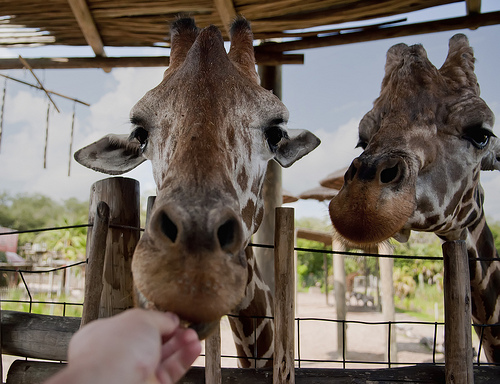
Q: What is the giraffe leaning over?
A: Fence.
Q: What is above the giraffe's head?
A: Roof.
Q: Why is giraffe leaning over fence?
A: Food.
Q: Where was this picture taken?
A: Zoo.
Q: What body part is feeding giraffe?
A: Hand.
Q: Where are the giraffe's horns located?
A: Head.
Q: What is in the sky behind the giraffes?
A: Clouds.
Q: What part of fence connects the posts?
A: Wire.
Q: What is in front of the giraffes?
A: A fence.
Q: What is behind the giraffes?
A: Wooden posts.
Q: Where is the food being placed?
A: In the giraffe's mouth.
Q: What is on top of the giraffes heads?
A: Horns.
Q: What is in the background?
A: Green trees.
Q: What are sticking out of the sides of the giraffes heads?
A: Ears.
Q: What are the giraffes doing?
A: Feeding.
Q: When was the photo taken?
A: Daytime.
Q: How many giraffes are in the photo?
A: Two.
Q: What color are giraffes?
A: Brown.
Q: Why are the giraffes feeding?
A: They are hungry.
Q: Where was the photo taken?
A: Wildlife park.